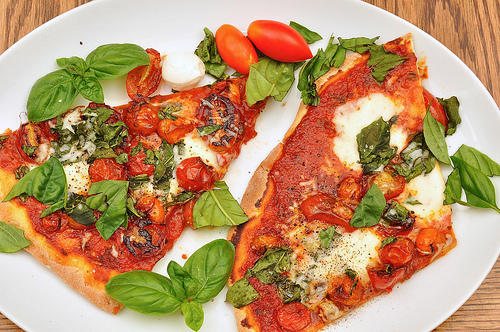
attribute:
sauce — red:
[9, 75, 259, 277]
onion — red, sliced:
[194, 92, 249, 146]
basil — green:
[23, 40, 152, 128]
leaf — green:
[74, 73, 104, 103]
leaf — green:
[86, 44, 148, 77]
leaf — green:
[103, 268, 182, 318]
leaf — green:
[451, 142, 486, 207]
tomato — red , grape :
[248, 21, 313, 63]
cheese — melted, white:
[399, 163, 446, 215]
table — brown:
[31, 3, 498, 327]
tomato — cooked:
[173, 156, 210, 198]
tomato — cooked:
[119, 101, 160, 140]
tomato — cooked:
[87, 150, 126, 188]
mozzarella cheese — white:
[158, 47, 208, 98]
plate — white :
[2, 1, 499, 328]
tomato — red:
[203, 17, 344, 80]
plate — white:
[63, 26, 476, 299]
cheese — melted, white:
[289, 93, 443, 293]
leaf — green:
[99, 271, 189, 315]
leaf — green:
[416, 100, 456, 170]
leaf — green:
[26, 67, 76, 122]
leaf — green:
[144, 241, 250, 305]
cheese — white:
[155, 49, 210, 91]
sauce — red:
[293, 130, 325, 159]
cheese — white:
[58, 145, 89, 184]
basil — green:
[351, 186, 385, 226]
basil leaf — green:
[23, 40, 150, 112]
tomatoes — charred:
[176, 153, 216, 191]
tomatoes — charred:
[125, 97, 163, 137]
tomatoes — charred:
[91, 152, 128, 182]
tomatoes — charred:
[126, 137, 154, 179]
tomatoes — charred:
[298, 190, 355, 227]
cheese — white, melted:
[277, 217, 391, 309]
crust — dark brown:
[1, 194, 70, 259]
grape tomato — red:
[124, 42, 161, 106]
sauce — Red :
[283, 164, 301, 182]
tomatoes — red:
[212, 21, 262, 77]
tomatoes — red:
[244, 16, 318, 64]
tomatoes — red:
[91, 99, 188, 199]